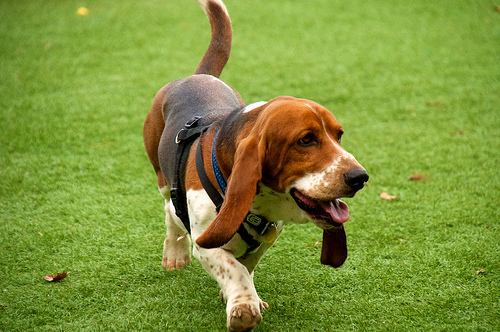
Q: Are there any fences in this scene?
A: No, there are no fences.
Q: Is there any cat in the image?
A: No, there are no cats.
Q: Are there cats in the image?
A: No, there are no cats.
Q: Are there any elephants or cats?
A: No, there are no cats or elephants.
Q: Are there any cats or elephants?
A: No, there are no cats or elephants.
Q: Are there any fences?
A: No, there are no fences.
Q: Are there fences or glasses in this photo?
A: No, there are no fences or glasses.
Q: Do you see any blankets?
A: No, there are no blankets.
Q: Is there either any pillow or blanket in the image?
A: No, there are no blankets or pillows.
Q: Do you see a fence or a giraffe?
A: No, there are no fences or giraffes.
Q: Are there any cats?
A: No, there are no cats.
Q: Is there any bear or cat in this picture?
A: No, there are no cats or bears.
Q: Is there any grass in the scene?
A: Yes, there is grass.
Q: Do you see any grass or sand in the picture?
A: Yes, there is grass.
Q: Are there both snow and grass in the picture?
A: No, there is grass but no snow.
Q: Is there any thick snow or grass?
A: Yes, there is thick grass.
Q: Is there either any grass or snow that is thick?
A: Yes, the grass is thick.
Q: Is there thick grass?
A: Yes, there is thick grass.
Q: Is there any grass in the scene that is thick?
A: Yes, there is grass that is thick.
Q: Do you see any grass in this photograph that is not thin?
A: Yes, there is thick grass.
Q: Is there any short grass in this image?
A: Yes, there is short grass.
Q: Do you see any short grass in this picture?
A: Yes, there is short grass.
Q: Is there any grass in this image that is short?
A: Yes, there is grass that is short.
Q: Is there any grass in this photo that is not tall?
A: Yes, there is short grass.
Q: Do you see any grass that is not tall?
A: Yes, there is short grass.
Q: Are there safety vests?
A: No, there are no safety vests.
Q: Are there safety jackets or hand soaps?
A: No, there are no safety jackets or hand soaps.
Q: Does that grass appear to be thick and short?
A: Yes, the grass is thick and short.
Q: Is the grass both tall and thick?
A: No, the grass is thick but short.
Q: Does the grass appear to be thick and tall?
A: No, the grass is thick but short.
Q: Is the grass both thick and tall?
A: No, the grass is thick but short.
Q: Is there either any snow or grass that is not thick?
A: No, there is grass but it is thick.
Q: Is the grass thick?
A: Yes, the grass is thick.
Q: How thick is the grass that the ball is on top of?
A: The grass is thick.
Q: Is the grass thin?
A: No, the grass is thick.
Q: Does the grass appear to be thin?
A: No, the grass is thick.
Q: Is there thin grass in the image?
A: No, there is grass but it is thick.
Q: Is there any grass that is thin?
A: No, there is grass but it is thick.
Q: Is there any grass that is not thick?
A: No, there is grass but it is thick.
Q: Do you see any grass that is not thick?
A: No, there is grass but it is thick.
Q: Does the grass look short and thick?
A: Yes, the grass is short and thick.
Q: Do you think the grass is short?
A: Yes, the grass is short.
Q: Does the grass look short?
A: Yes, the grass is short.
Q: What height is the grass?
A: The grass is short.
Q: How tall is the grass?
A: The grass is short.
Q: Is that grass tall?
A: No, the grass is short.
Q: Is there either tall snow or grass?
A: No, there is grass but it is short.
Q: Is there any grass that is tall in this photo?
A: No, there is grass but it is short.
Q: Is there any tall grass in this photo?
A: No, there is grass but it is short.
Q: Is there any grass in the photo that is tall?
A: No, there is grass but it is short.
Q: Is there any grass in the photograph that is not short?
A: No, there is grass but it is short.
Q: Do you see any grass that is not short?
A: No, there is grass but it is short.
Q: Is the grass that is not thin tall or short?
A: The grass is short.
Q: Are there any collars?
A: Yes, there is a collar.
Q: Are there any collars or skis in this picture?
A: Yes, there is a collar.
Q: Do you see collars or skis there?
A: Yes, there is a collar.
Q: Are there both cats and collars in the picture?
A: No, there is a collar but no cats.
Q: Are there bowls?
A: No, there are no bowls.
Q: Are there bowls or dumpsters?
A: No, there are no bowls or dumpsters.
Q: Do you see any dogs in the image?
A: Yes, there is a dog.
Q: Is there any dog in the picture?
A: Yes, there is a dog.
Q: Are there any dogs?
A: Yes, there is a dog.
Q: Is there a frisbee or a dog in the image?
A: Yes, there is a dog.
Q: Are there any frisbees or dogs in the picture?
A: Yes, there is a dog.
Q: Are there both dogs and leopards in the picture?
A: No, there is a dog but no leopards.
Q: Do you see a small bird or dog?
A: Yes, there is a small dog.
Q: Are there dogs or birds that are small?
A: Yes, the dog is small.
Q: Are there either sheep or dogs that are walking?
A: Yes, the dog is walking.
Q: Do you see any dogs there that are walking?
A: Yes, there is a dog that is walking.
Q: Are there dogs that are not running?
A: Yes, there is a dog that is walking.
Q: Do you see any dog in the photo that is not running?
A: Yes, there is a dog that is walking .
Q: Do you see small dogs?
A: Yes, there is a small dog.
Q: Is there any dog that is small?
A: Yes, there is a dog that is small.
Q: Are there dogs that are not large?
A: Yes, there is a small dog.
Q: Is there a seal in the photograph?
A: No, there are no seals.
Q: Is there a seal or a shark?
A: No, there are no seals or sharks.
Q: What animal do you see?
A: The animal is a dog.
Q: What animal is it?
A: The animal is a dog.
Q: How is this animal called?
A: This is a dog.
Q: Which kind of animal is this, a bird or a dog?
A: This is a dog.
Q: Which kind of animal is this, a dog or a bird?
A: This is a dog.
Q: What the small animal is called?
A: The animal is a dog.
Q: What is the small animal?
A: The animal is a dog.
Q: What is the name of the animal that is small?
A: The animal is a dog.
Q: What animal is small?
A: The animal is a dog.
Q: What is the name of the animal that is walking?
A: The animal is a dog.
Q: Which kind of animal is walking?
A: The animal is a dog.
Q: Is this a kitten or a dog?
A: This is a dog.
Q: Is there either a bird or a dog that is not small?
A: No, there is a dog but it is small.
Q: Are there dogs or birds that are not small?
A: No, there is a dog but it is small.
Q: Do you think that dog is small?
A: Yes, the dog is small.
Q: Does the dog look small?
A: Yes, the dog is small.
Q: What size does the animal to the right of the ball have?
A: The dog has small size.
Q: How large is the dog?
A: The dog is small.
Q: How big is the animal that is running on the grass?
A: The dog is small.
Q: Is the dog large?
A: No, the dog is small.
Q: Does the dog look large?
A: No, the dog is small.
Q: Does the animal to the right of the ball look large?
A: No, the dog is small.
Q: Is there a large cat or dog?
A: No, there is a dog but it is small.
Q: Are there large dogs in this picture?
A: No, there is a dog but it is small.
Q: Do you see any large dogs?
A: No, there is a dog but it is small.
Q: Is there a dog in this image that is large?
A: No, there is a dog but it is small.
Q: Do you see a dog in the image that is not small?
A: No, there is a dog but it is small.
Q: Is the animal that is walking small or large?
A: The dog is small.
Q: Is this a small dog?
A: Yes, this is a small dog.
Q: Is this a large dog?
A: No, this is a small dog.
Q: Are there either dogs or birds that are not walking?
A: No, there is a dog but it is walking.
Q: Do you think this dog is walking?
A: Yes, the dog is walking.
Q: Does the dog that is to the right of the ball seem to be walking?
A: Yes, the dog is walking.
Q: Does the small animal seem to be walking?
A: Yes, the dog is walking.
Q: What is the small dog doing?
A: The dog is walking.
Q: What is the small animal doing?
A: The dog is walking.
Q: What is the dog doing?
A: The dog is walking.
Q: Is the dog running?
A: No, the dog is walking.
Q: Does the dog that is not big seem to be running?
A: No, the dog is walking.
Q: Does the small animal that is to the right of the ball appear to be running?
A: No, the dog is walking.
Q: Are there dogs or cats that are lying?
A: No, there is a dog but it is walking.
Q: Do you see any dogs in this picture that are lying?
A: No, there is a dog but it is walking.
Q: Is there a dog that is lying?
A: No, there is a dog but it is walking.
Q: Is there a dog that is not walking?
A: No, there is a dog but it is walking.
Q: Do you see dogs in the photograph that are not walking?
A: No, there is a dog but it is walking.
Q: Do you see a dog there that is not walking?
A: No, there is a dog but it is walking.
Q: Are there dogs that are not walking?
A: No, there is a dog but it is walking.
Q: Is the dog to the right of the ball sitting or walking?
A: The dog is walking.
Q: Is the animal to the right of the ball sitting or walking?
A: The dog is walking.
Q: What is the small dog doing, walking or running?
A: The dog is walking.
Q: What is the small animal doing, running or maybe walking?
A: The dog is walking.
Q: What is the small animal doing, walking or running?
A: The dog is walking.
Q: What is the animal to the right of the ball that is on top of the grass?
A: The animal is a dog.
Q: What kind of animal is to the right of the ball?
A: The animal is a dog.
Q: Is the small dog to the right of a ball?
A: Yes, the dog is to the right of a ball.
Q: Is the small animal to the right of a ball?
A: Yes, the dog is to the right of a ball.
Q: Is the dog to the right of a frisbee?
A: No, the dog is to the right of a ball.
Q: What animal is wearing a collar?
A: The animal is a dog.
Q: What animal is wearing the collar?
A: The animal is a dog.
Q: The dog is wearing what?
A: The dog is wearing a collar.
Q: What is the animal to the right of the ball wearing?
A: The dog is wearing a collar.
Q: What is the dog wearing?
A: The dog is wearing a collar.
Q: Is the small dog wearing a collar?
A: Yes, the dog is wearing a collar.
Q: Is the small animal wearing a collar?
A: Yes, the dog is wearing a collar.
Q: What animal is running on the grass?
A: The dog is running on the grass.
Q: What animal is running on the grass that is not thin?
A: The animal is a dog.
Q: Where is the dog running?
A: The dog is running on the grass.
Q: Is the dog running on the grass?
A: Yes, the dog is running on the grass.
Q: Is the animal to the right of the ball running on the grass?
A: Yes, the dog is running on the grass.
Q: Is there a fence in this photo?
A: No, there are no fences.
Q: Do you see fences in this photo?
A: No, there are no fences.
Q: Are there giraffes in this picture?
A: No, there are no giraffes.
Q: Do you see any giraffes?
A: No, there are no giraffes.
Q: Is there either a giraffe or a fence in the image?
A: No, there are no giraffes or fences.